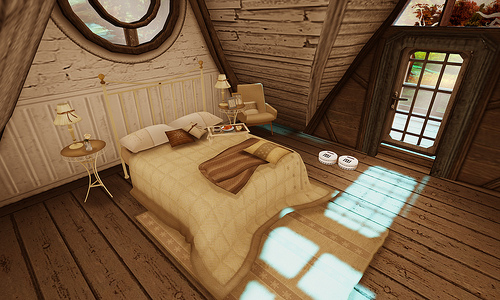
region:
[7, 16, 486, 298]
cartoon photograph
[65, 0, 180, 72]
round window above bed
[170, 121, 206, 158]
two throw pillows at top of bed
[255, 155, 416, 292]
sun light shining through door ont to floor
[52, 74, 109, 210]
end table with a lamp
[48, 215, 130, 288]
brown wooden floor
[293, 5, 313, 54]
broken pieces of wood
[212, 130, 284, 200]
blanket and pillow on top of bed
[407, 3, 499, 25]
trees can be seen through window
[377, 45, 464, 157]
door with glass panes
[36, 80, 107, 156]
a lamp on a table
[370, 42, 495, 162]
a brown wooden door with windows on it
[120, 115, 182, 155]
a white pillow on a bed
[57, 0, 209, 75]
a round window in a room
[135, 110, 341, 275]
a blanket on a bed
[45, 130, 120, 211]
a night stand near a bed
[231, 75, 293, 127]
a chair in a room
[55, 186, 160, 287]
a wooden floor in a room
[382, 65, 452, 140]
windows on a door in a room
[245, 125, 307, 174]
a small pillow on a bed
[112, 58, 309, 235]
bed in the room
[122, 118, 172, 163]
pillow on the bed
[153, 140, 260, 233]
blanket on the bed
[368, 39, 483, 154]
window in the room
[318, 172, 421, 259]
light on the ground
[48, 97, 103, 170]
lamp next to bed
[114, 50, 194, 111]
wall behind the bed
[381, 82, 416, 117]
handle on the door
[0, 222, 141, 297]
lines on the ground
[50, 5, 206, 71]
round shape above bed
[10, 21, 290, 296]
Wall is brown color.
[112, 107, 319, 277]
Cot is in middle of the room.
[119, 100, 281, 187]
Five pillows are in the cot.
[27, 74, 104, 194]
Lamp is in the side table.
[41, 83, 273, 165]
Two lamps are in sides of the cot.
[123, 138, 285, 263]
Quilt is brown color.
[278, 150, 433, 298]
Sunlight reflection on floor.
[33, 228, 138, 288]
Floor is brown color.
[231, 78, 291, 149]
Chair is in the corner of the room.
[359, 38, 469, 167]
Door is brown color.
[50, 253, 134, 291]
The floor is made from wood.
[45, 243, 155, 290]
The floor is brown in color.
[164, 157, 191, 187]
The blanket on the bed is ivory.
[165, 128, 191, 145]
The pillow on the bed is brown.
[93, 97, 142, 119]
The bedroom wall is white.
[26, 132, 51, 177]
The bedroom wall is made of wood.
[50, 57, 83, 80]
The bedroom wall is made of brick.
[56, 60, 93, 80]
The bedroom wall is white.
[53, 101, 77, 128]
The lampshade is ivory and brown.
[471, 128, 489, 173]
The wall is brown in color.